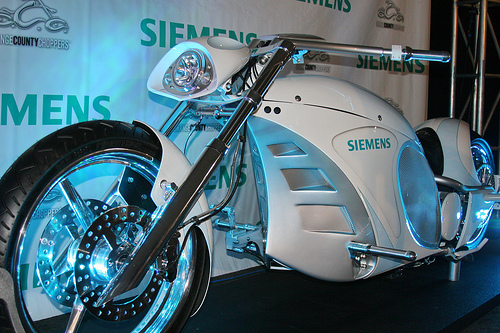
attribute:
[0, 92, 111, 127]
logo — siemens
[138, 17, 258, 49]
logo — siemens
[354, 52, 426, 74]
logo — siemens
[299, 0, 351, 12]
logo — siemens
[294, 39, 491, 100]
handlebars — shiny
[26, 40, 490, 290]
motorcycle — inside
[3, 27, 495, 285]
motorcycle — brand new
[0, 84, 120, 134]
logo — siemens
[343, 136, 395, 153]
logo — siemens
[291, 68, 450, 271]
tank — white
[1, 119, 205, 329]
tire — black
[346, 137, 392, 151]
word — green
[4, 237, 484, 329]
platform — black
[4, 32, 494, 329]
bike — white, glossy, new, displayed, unused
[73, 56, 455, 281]
motorcycle — white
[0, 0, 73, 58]
emblem — Orange County Choppers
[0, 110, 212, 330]
wheel — clean, black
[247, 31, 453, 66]
handlebars — gray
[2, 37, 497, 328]
motorcycle — white, displayed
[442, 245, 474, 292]
stand — foot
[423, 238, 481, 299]
stand — foot